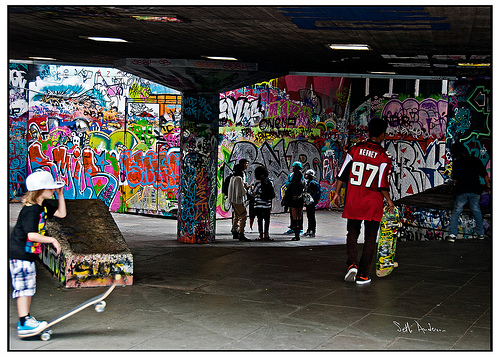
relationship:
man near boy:
[328, 111, 405, 286] [15, 166, 72, 333]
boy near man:
[15, 166, 72, 333] [328, 111, 405, 286]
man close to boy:
[328, 111, 405, 286] [15, 166, 72, 333]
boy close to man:
[15, 166, 72, 333] [328, 111, 405, 286]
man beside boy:
[328, 111, 405, 286] [15, 166, 72, 333]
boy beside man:
[15, 166, 72, 333] [328, 111, 405, 286]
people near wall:
[225, 143, 326, 239] [18, 60, 493, 226]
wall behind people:
[18, 60, 493, 226] [225, 143, 326, 239]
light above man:
[322, 42, 375, 55] [328, 111, 405, 286]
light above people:
[322, 42, 375, 55] [225, 143, 326, 239]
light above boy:
[322, 42, 375, 55] [15, 166, 72, 333]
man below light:
[328, 111, 405, 286] [322, 42, 375, 55]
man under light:
[328, 111, 405, 286] [322, 42, 375, 55]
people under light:
[225, 143, 326, 239] [322, 42, 375, 55]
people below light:
[225, 143, 326, 239] [322, 42, 375, 55]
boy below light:
[15, 166, 72, 333] [322, 42, 375, 55]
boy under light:
[15, 166, 72, 333] [322, 42, 375, 55]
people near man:
[225, 143, 326, 239] [328, 111, 405, 286]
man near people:
[328, 111, 405, 286] [225, 143, 326, 239]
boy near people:
[15, 166, 72, 333] [225, 143, 326, 239]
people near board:
[225, 143, 326, 239] [373, 200, 408, 278]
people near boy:
[225, 143, 326, 239] [15, 166, 72, 333]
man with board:
[328, 111, 405, 286] [373, 200, 408, 278]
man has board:
[328, 111, 405, 286] [373, 200, 408, 278]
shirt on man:
[339, 142, 390, 219] [328, 111, 405, 286]